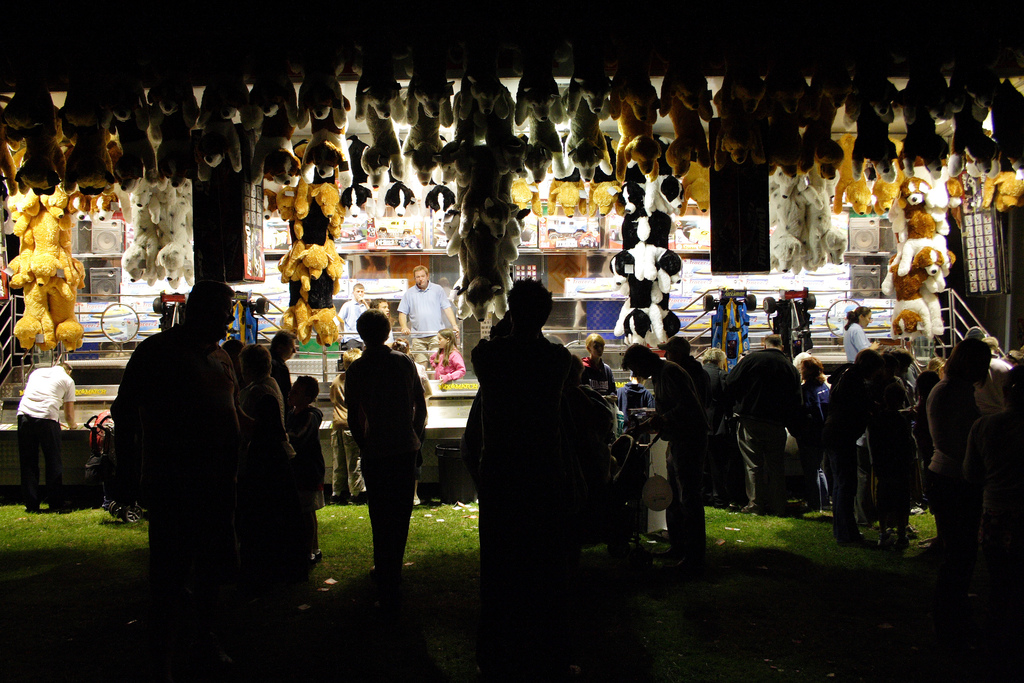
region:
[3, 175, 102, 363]
the pushes are yellow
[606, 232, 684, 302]
a white and black plush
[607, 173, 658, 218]
a white and black plush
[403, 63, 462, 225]
plushes hanging from roof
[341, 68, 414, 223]
plushes hanging from roof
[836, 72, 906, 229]
plushes hanging from roof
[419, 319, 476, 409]
person wearing pink top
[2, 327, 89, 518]
person with white shirt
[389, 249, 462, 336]
the man has blue shirt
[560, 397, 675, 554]
Person pushing a stroller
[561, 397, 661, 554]
Person is pushing a stroller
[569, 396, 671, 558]
Person is pushing a baby stroller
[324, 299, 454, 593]
Person standing on grass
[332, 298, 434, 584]
Person is standing on grass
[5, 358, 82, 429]
Person wearing a shirt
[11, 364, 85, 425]
Person is wearing a shirt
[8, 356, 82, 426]
Person wearing a white shirt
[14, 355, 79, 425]
Person is wearing a white shirt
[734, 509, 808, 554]
the lawn is green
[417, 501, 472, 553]
the grass is low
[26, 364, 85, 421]
a white shirt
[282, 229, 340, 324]
a teddy bear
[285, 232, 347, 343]
the teddy bear is brown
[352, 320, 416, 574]
a person standing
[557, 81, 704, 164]
hanging stuffed animals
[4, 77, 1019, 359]
prizes are hanging from the roof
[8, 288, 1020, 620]
people are at a carnival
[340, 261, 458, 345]
workers are wearing light blue shirts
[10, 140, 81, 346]
these stuffed animals are very big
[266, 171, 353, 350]
these stuffed animals are very big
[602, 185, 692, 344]
these stuffed animals are black and white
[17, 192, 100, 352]
stuffed animals are orange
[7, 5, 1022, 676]
ir is night time at the carnival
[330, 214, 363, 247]
item on the shelf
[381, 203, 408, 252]
item on the shelf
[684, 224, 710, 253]
item on the shelf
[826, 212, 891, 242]
item on the shelf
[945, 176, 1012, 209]
item on the shelf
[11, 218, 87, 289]
item on the shelf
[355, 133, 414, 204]
item on the shelf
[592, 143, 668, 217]
item on the shelf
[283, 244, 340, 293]
item on the shelf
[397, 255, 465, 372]
man in a light blue shirt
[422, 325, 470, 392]
girl in a pink shirt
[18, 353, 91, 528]
man in a white shirt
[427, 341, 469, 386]
pink long sleeved shirt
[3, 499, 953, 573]
green colored grass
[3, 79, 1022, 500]
game stand at a carnival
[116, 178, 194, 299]
white bears hanging in the game booth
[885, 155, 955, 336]
white and brown stuffed dogs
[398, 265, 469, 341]
man wearing blue shirt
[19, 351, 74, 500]
man wearing white shirt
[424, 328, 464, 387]
young girl wearing pink shirt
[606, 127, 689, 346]
black and white dogs hanging in the booth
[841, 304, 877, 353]
woman wearing light blue shirt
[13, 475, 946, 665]
grass in front of the booth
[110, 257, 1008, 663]
people standing in front of the booth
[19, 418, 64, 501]
black pants man is wearing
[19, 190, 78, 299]
yellow stuffed animal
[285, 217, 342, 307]
yellow stuffed animal